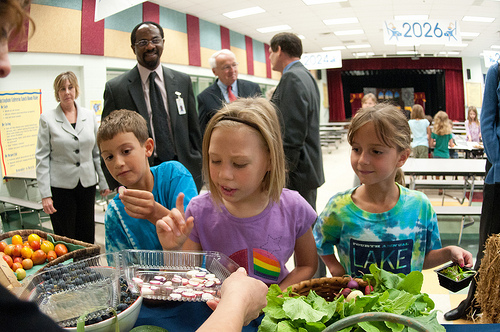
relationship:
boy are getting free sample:
[95, 108, 197, 268] [0, 227, 70, 281]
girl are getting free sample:
[155, 97, 319, 301] [30, 260, 140, 327]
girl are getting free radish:
[311, 102, 475, 295] [130, 270, 222, 300]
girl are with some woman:
[155, 97, 319, 301] [35, 69, 105, 246]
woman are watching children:
[35, 69, 105, 246] [88, 100, 445, 277]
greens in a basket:
[254, 263, 446, 330] [273, 268, 367, 301]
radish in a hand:
[115, 184, 129, 198] [119, 184, 156, 222]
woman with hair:
[35, 69, 105, 246] [347, 104, 418, 141]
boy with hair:
[93, 103, 223, 255] [97, 117, 197, 147]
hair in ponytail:
[350, 106, 414, 185] [394, 167, 405, 182]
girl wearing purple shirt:
[155, 97, 319, 301] [186, 180, 311, 265]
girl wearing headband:
[148, 94, 320, 309] [213, 116, 267, 135]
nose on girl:
[214, 162, 233, 180] [148, 94, 320, 309]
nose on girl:
[353, 151, 373, 164] [304, 98, 476, 295]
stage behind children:
[335, 115, 467, 134] [89, 112, 451, 267]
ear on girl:
[395, 144, 412, 168] [304, 98, 476, 295]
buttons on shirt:
[74, 136, 78, 141] [30, 104, 110, 196]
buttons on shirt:
[74, 147, 84, 157] [30, 104, 110, 196]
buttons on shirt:
[72, 158, 85, 167] [30, 104, 110, 196]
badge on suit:
[173, 90, 186, 114] [101, 64, 204, 179]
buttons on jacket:
[74, 134, 77, 142] [30, 102, 112, 199]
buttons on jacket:
[74, 149, 79, 154] [30, 102, 112, 199]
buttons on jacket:
[75, 162, 80, 168] [30, 102, 112, 199]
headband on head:
[213, 116, 267, 135] [187, 95, 293, 205]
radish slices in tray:
[179, 258, 218, 283] [35, 248, 239, 314]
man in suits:
[99, 21, 203, 196] [107, 64, 342, 201]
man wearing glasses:
[99, 19, 213, 182] [103, 15, 201, 174]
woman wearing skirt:
[35, 69, 105, 246] [44, 180, 101, 246]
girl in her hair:
[155, 97, 319, 301] [193, 93, 283, 200]